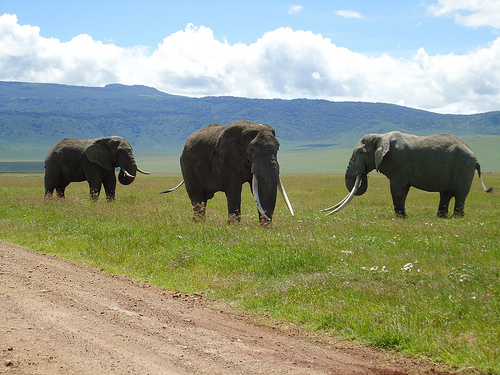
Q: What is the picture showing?
A: It is showing a road.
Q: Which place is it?
A: It is a road.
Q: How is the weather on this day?
A: It is cloudy.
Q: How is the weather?
A: It is cloudy.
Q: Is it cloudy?
A: Yes, it is cloudy.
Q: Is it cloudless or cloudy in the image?
A: It is cloudy.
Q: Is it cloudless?
A: No, it is cloudy.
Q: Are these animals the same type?
A: Yes, all the animals are elephants.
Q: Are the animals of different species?
A: No, all the animals are elephants.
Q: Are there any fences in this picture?
A: No, there are no fences.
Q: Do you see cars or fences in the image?
A: No, there are no fences or cars.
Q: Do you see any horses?
A: No, there are no horses.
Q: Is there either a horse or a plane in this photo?
A: No, there are no horses or airplanes.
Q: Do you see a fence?
A: No, there are no fences.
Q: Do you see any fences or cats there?
A: No, there are no fences or cats.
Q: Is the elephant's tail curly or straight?
A: The tail is curly.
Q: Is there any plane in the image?
A: No, there are no airplanes.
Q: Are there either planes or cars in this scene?
A: No, there are no planes or cars.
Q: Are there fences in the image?
A: No, there are no fences.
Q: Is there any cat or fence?
A: No, there are no fences or cats.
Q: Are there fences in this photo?
A: No, there are no fences.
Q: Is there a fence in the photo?
A: No, there are no fences.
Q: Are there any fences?
A: No, there are no fences.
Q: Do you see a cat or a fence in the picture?
A: No, there are no fences or cats.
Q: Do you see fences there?
A: No, there are no fences.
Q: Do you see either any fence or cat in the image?
A: No, there are no fences or cats.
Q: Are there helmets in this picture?
A: No, there are no helmets.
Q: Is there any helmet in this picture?
A: No, there are no helmets.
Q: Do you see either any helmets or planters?
A: No, there are no helmets or planters.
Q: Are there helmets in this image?
A: No, there are no helmets.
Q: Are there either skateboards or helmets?
A: No, there are no helmets or skateboards.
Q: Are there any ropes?
A: No, there are no ropes.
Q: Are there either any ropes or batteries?
A: No, there are no ropes or batteries.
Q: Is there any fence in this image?
A: No, there are no fences.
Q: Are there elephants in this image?
A: Yes, there is an elephant.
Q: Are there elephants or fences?
A: Yes, there is an elephant.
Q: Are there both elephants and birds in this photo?
A: No, there is an elephant but no birds.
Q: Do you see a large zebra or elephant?
A: Yes, there is a large elephant.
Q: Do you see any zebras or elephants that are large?
A: Yes, the elephant is large.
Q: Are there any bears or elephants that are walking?
A: Yes, the elephant is walking.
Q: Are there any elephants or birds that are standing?
A: Yes, the elephant is standing.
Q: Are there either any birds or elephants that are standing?
A: Yes, the elephant is standing.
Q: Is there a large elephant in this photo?
A: Yes, there is a large elephant.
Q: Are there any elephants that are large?
A: Yes, there is an elephant that is large.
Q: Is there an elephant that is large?
A: Yes, there is an elephant that is large.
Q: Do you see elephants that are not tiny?
A: Yes, there is a large elephant.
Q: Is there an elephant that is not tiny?
A: Yes, there is a large elephant.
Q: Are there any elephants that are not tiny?
A: Yes, there is a large elephant.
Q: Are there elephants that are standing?
A: Yes, there is an elephant that is standing.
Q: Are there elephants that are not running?
A: Yes, there is an elephant that is standing.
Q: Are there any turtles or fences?
A: No, there are no fences or turtles.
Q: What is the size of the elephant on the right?
A: The elephant is large.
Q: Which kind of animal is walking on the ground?
A: The animal is an elephant.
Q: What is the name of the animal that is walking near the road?
A: The animal is an elephant.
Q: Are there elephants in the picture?
A: Yes, there is an elephant.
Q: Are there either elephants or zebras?
A: Yes, there is an elephant.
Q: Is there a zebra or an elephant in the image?
A: Yes, there is an elephant.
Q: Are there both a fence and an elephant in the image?
A: No, there is an elephant but no fences.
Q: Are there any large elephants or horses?
A: Yes, there is a large elephant.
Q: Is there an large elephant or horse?
A: Yes, there is a large elephant.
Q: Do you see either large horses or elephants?
A: Yes, there is a large elephant.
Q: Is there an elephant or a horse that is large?
A: Yes, the elephant is large.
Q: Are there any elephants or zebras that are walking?
A: Yes, the elephant is walking.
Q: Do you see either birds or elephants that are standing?
A: Yes, the elephant is standing.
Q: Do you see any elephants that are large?
A: Yes, there is a large elephant.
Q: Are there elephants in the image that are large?
A: Yes, there is an elephant that is large.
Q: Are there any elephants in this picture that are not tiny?
A: Yes, there is a large elephant.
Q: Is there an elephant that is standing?
A: Yes, there is an elephant that is standing.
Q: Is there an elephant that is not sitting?
A: Yes, there is an elephant that is standing.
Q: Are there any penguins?
A: No, there are no penguins.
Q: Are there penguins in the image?
A: No, there are no penguins.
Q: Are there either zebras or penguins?
A: No, there are no penguins or zebras.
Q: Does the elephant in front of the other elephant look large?
A: Yes, the elephant is large.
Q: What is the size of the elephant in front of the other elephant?
A: The elephant is large.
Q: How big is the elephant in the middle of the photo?
A: The elephant is large.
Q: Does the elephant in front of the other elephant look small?
A: No, the elephant is large.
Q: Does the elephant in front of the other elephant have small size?
A: No, the elephant is large.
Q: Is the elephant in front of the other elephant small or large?
A: The elephant is large.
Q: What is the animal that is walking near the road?
A: The animal is an elephant.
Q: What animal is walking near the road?
A: The animal is an elephant.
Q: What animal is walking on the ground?
A: The elephant is walking on the ground.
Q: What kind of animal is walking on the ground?
A: The animal is an elephant.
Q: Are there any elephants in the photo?
A: Yes, there is an elephant.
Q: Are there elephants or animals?
A: Yes, there is an elephant.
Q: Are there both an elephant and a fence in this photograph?
A: No, there is an elephant but no fences.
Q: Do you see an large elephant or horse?
A: Yes, there is a large elephant.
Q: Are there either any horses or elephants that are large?
A: Yes, the elephant is large.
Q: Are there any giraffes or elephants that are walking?
A: Yes, the elephant is walking.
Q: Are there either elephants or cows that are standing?
A: Yes, the elephant is standing.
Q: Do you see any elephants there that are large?
A: Yes, there is a large elephant.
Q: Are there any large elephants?
A: Yes, there is a large elephant.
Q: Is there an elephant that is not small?
A: Yes, there is a large elephant.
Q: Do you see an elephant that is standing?
A: Yes, there is an elephant that is standing.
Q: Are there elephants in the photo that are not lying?
A: Yes, there is an elephant that is standing.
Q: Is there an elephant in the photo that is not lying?
A: Yes, there is an elephant that is standing.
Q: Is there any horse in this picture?
A: No, there are no horses.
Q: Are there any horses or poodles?
A: No, there are no horses or poodles.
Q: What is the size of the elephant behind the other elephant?
A: The elephant is large.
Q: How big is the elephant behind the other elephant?
A: The elephant is large.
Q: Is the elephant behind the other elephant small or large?
A: The elephant is large.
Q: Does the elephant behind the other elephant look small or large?
A: The elephant is large.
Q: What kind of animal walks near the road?
A: The animal is an elephant.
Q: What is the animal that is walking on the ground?
A: The animal is an elephant.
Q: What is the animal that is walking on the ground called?
A: The animal is an elephant.